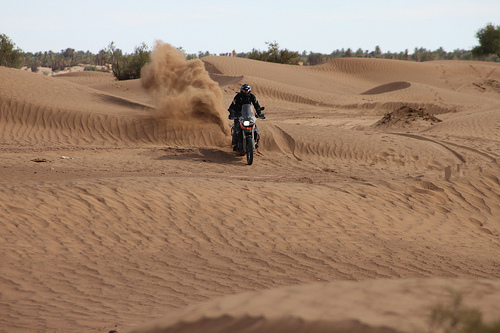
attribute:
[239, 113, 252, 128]
headlamp — bright 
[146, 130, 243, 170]
shadow — cast 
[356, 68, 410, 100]
spot — small 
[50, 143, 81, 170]
object — random 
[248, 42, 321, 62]
trees — in the back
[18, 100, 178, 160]
bank — raised 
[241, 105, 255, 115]
screen — protective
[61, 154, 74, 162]
object — white 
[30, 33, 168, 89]
trees — green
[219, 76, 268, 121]
man — riding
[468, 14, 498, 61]
tree — large